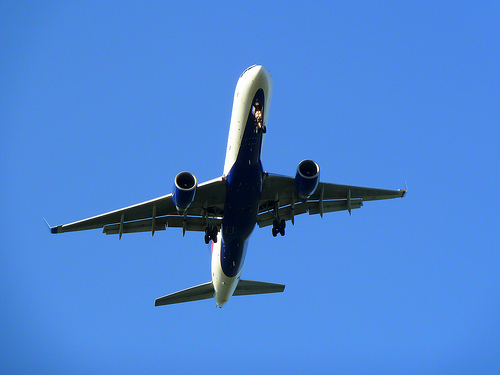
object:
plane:
[42, 63, 406, 307]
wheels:
[272, 219, 281, 238]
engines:
[172, 169, 199, 219]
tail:
[152, 279, 286, 308]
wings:
[44, 159, 406, 247]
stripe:
[208, 240, 214, 260]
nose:
[245, 63, 269, 77]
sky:
[0, 0, 500, 373]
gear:
[202, 207, 220, 231]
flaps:
[101, 214, 224, 239]